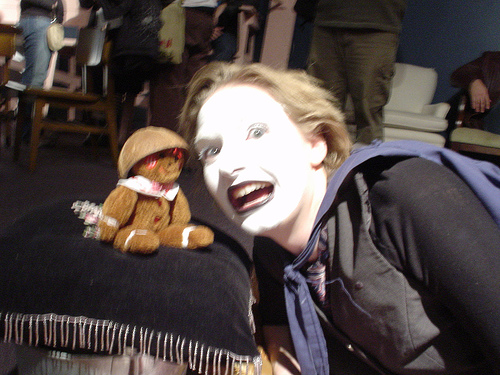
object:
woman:
[174, 59, 500, 375]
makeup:
[194, 83, 307, 233]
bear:
[99, 124, 214, 254]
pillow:
[0, 169, 260, 374]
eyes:
[157, 154, 165, 160]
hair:
[171, 59, 361, 180]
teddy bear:
[70, 125, 216, 253]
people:
[448, 51, 499, 133]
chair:
[376, 63, 452, 154]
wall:
[289, 0, 495, 130]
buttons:
[151, 216, 164, 225]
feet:
[122, 231, 162, 252]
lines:
[181, 227, 198, 248]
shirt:
[250, 141, 499, 374]